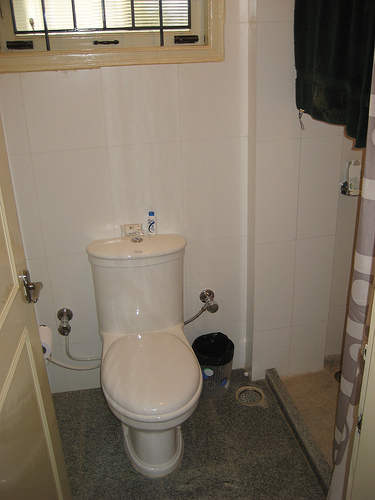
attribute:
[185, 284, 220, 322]
plumbing — right sided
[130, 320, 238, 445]
lid — white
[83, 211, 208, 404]
toilet — closed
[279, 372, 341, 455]
floor — tan, shower floor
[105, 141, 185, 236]
tiles — off white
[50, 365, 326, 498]
floor — tile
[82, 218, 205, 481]
toilet — shiny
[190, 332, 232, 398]
trashcan — spotted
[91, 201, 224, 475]
toilet — white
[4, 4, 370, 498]
bathroom — plain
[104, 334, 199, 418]
toilet seat — white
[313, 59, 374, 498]
shower curtain — patterned, white, tan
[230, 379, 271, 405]
drain — floor drain, metal, silver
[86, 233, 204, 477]
toilet — shiny